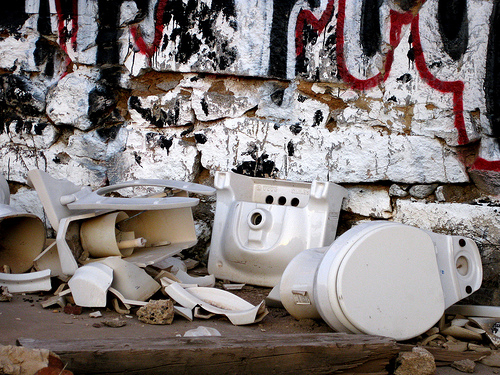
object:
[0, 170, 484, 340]
ceramic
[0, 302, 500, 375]
ground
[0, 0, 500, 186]
graffiti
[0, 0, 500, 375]
toilet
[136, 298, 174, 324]
rock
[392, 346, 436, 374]
rock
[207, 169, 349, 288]
sink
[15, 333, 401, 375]
wood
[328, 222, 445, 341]
toilet`s seat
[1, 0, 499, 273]
background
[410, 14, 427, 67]
coloring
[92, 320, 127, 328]
rock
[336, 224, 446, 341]
lid